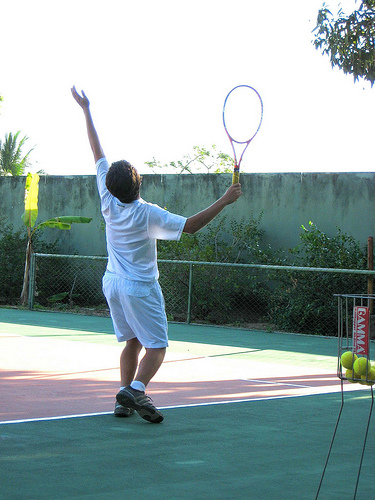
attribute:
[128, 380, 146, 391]
sock — short, white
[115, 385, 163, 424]
tennis shoe — brown and black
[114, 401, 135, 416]
tennis shoe — brown and black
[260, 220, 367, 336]
bush — large, green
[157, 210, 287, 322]
bush — green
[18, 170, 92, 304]
plant — green leafed, large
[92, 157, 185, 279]
t-shirt — man's, short sleeved, white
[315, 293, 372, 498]
basket — metal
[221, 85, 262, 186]
tennis racket — red black and yellow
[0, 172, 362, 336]
wall — tall, concrete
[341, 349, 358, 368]
tennis ball — bright, yellow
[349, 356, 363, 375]
tennis ball — yellow, bright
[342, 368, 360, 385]
tennis ball — bright, yellow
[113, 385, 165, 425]
sneaker — brown, black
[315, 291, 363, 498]
basket — metal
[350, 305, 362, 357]
sign — red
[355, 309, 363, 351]
letters — white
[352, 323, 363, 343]
m's — white, double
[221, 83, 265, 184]
tennis racket — blue, red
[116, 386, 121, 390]
sock — short , white 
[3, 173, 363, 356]
wall — white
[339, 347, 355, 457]
tennis balls — green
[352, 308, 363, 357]
sign — red, white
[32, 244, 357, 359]
fence — chain link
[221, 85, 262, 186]
racket — lightweight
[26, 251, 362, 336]
fence — short, chain link, long, small, metal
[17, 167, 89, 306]
tree — small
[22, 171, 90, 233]
leaves — large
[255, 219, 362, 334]
shrub — large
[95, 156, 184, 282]
shirt — white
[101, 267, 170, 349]
shorts — men's, white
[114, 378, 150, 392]
socks — white